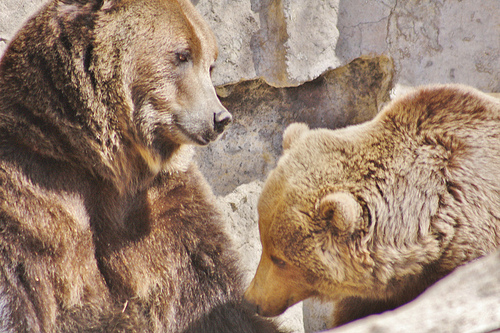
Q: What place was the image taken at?
A: It was taken at the zoo.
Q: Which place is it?
A: It is a zoo.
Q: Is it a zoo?
A: Yes, it is a zoo.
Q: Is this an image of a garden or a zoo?
A: It is showing a zoo.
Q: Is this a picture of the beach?
A: No, the picture is showing the zoo.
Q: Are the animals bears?
A: Yes, all the animals are bears.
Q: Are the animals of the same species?
A: Yes, all the animals are bears.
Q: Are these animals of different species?
A: No, all the animals are bears.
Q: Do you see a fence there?
A: No, there are no fences.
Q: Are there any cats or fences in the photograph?
A: No, there are no fences or cats.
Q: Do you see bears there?
A: Yes, there is a bear.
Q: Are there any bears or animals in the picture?
A: Yes, there is a bear.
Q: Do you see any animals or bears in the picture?
A: Yes, there is a bear.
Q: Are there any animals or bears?
A: Yes, there is a bear.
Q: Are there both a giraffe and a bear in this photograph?
A: No, there is a bear but no giraffes.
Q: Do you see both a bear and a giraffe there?
A: No, there is a bear but no giraffes.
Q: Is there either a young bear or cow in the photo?
A: Yes, there is a young bear.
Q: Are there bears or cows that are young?
A: Yes, the bear is young.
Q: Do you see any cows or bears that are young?
A: Yes, the bear is young.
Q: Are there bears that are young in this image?
A: Yes, there is a young bear.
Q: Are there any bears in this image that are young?
A: Yes, there is a bear that is young.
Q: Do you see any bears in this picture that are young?
A: Yes, there is a bear that is young.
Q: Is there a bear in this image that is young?
A: Yes, there is a bear that is young.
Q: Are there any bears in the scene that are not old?
A: Yes, there is an young bear.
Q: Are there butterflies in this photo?
A: No, there are no butterflies.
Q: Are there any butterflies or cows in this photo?
A: No, there are no butterflies or cows.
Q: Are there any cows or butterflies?
A: No, there are no butterflies or cows.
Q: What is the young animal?
A: The animal is a bear.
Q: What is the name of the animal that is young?
A: The animal is a bear.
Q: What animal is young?
A: The animal is a bear.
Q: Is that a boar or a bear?
A: That is a bear.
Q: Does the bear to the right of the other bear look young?
A: Yes, the bear is young.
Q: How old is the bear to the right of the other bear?
A: The bear is young.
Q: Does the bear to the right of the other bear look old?
A: No, the bear is young.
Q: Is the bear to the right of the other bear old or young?
A: The bear is young.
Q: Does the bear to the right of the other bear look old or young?
A: The bear is young.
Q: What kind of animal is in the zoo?
A: The animal is a bear.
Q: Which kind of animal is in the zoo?
A: The animal is a bear.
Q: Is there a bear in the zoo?
A: Yes, there is a bear in the zoo.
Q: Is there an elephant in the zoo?
A: No, there is a bear in the zoo.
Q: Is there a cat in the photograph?
A: No, there are no cats.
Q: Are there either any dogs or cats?
A: No, there are no cats or dogs.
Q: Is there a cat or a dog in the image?
A: No, there are no cats or dogs.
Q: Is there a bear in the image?
A: Yes, there is a bear.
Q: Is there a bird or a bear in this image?
A: Yes, there is a bear.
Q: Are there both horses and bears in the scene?
A: No, there is a bear but no horses.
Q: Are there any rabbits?
A: No, there are no rabbits.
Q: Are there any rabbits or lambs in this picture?
A: No, there are no rabbits or lambs.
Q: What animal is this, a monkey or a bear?
A: This is a bear.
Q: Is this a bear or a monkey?
A: This is a bear.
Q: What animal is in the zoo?
A: The bear is in the zoo.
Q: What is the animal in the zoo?
A: The animal is a bear.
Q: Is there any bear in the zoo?
A: Yes, there is a bear in the zoo.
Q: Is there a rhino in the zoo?
A: No, there is a bear in the zoo.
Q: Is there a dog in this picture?
A: No, there are no dogs.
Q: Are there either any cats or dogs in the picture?
A: No, there are no dogs or cats.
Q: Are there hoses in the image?
A: No, there are no hoses.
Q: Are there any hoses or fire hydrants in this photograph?
A: No, there are no hoses or fire hydrants.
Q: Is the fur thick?
A: Yes, the fur is thick.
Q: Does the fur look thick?
A: Yes, the fur is thick.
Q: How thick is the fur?
A: The fur is thick.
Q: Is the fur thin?
A: No, the fur is thick.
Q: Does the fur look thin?
A: No, the fur is thick.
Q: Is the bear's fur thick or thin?
A: The fur is thick.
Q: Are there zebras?
A: No, there are no zebras.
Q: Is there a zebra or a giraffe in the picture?
A: No, there are no zebras or giraffes.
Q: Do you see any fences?
A: No, there are no fences.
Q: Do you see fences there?
A: No, there are no fences.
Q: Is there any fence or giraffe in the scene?
A: No, there are no fences or giraffes.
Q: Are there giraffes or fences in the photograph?
A: No, there are no fences or giraffes.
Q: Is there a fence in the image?
A: No, there are no fences.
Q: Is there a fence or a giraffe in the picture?
A: No, there are no fences or giraffes.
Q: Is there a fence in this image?
A: No, there are no fences.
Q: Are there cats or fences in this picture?
A: No, there are no fences or cats.